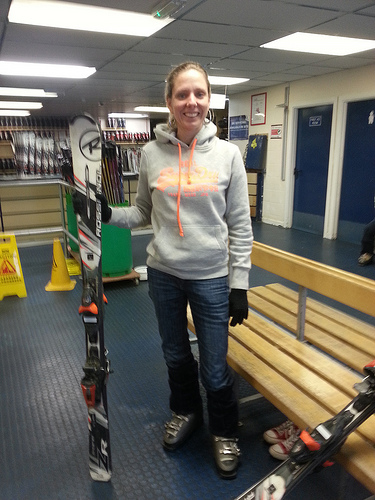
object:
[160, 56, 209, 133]
hair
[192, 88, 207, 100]
eye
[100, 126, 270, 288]
hoodie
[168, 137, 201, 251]
tie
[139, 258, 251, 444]
pants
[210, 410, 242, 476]
sneakers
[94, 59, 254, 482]
women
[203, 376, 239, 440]
leg warmers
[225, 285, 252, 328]
gloves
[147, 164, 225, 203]
print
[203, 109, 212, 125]
earrings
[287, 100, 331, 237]
door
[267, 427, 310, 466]
sneakers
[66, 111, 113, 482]
ski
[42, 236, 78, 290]
cone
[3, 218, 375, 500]
floor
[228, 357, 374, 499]
ski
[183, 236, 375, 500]
bench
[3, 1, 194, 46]
lights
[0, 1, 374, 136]
ceiling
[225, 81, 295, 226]
wall